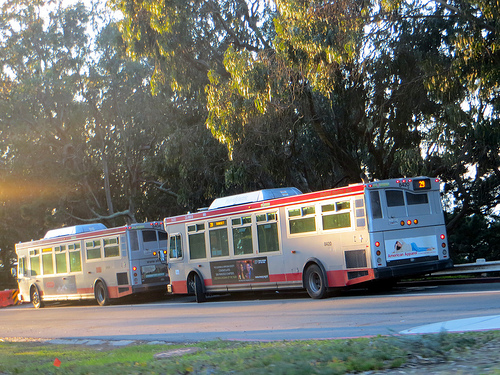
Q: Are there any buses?
A: Yes, there is a bus.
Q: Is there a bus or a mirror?
A: Yes, there is a bus.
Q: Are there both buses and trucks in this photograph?
A: No, there is a bus but no trucks.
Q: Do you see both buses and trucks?
A: No, there is a bus but no trucks.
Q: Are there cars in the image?
A: No, there are no cars.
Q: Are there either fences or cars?
A: No, there are no cars or fences.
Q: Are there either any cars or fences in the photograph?
A: No, there are no cars or fences.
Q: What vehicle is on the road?
A: The vehicle is a bus.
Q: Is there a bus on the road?
A: Yes, there is a bus on the road.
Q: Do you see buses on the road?
A: Yes, there is a bus on the road.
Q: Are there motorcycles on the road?
A: No, there is a bus on the road.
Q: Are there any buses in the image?
A: Yes, there is a bus.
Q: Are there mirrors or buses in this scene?
A: Yes, there is a bus.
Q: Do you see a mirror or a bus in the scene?
A: Yes, there is a bus.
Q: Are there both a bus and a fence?
A: No, there is a bus but no fences.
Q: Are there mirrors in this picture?
A: No, there are no mirrors.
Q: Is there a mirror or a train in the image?
A: No, there are no mirrors or trains.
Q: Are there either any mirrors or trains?
A: No, there are no mirrors or trains.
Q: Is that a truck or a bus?
A: That is a bus.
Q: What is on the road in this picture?
A: The bus is on the road.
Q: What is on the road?
A: The bus is on the road.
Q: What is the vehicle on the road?
A: The vehicle is a bus.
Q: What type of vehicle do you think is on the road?
A: The vehicle is a bus.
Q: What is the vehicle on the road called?
A: The vehicle is a bus.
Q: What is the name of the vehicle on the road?
A: The vehicle is a bus.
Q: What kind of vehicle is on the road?
A: The vehicle is a bus.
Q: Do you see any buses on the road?
A: Yes, there is a bus on the road.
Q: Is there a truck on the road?
A: No, there is a bus on the road.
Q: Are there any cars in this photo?
A: No, there are no cars.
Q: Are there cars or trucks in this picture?
A: No, there are no cars or trucks.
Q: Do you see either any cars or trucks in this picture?
A: No, there are no cars or trucks.